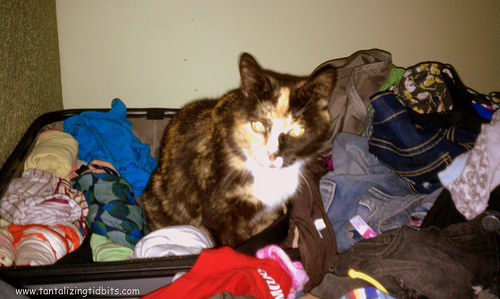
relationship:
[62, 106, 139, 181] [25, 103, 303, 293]
clothing in suitcase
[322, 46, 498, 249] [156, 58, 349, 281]
clothes next to cat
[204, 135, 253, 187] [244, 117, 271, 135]
whiskers above eye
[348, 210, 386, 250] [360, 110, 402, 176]
tag on clothing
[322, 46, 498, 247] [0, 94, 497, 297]
clothes on bed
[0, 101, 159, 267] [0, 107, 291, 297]
clothing in suitcase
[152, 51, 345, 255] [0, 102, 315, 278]
cat in a chest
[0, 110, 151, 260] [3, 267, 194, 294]
clothing in suitcase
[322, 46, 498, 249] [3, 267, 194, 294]
clothes in suitcase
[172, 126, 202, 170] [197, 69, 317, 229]
fur on cat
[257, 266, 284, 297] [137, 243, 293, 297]
text on shirt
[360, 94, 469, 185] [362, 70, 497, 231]
clothing on clothing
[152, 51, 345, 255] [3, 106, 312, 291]
cat sitting on suitcase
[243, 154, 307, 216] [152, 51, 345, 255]
spot on cat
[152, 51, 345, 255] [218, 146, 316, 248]
cat has chest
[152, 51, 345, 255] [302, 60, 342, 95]
cat has ear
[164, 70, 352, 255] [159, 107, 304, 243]
cat has eye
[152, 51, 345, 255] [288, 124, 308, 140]
cat has eye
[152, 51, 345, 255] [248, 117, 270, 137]
cat has eye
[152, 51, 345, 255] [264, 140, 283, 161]
cat has nose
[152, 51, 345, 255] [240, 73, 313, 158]
cat has face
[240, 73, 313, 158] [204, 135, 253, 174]
face has whiskers